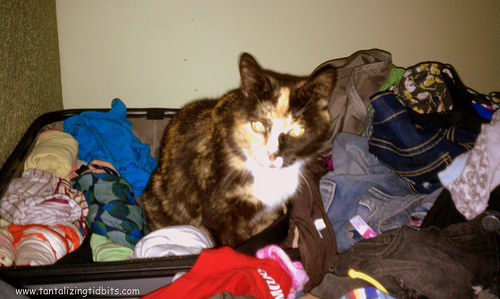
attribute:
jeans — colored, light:
[316, 118, 442, 246]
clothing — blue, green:
[81, 164, 153, 259]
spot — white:
[243, 154, 307, 216]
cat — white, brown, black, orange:
[139, 50, 335, 245]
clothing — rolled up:
[0, 110, 151, 260]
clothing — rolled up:
[327, 51, 498, 217]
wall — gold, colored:
[0, 0, 62, 167]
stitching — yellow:
[372, 138, 449, 158]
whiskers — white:
[223, 145, 263, 186]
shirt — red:
[137, 243, 293, 297]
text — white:
[257, 266, 284, 297]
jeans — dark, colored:
[365, 87, 481, 194]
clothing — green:
[88, 231, 133, 260]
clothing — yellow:
[27, 125, 75, 176]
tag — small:
[348, 210, 386, 250]